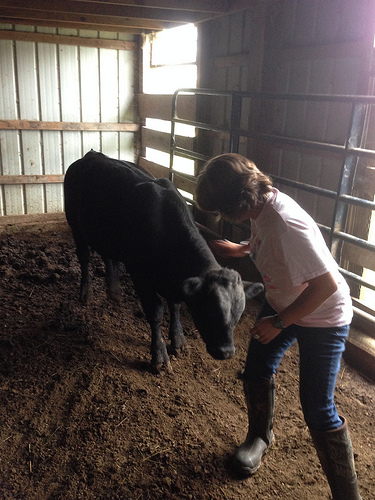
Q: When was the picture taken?
A: During the day.